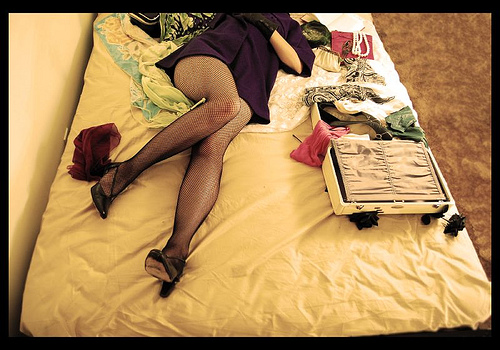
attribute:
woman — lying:
[124, 19, 286, 242]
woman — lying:
[145, 25, 297, 275]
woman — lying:
[173, 20, 300, 278]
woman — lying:
[118, 28, 300, 248]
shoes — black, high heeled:
[54, 175, 216, 303]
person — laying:
[114, 36, 333, 269]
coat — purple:
[181, 35, 290, 112]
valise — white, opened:
[314, 123, 443, 236]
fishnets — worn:
[118, 82, 267, 263]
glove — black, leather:
[235, 13, 280, 35]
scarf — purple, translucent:
[73, 134, 121, 174]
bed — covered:
[47, 47, 455, 316]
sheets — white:
[197, 205, 437, 332]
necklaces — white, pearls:
[338, 24, 379, 63]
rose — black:
[428, 207, 474, 243]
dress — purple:
[173, 17, 306, 114]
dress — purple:
[191, 27, 333, 144]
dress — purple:
[199, 21, 324, 111]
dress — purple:
[191, 25, 321, 116]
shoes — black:
[91, 182, 207, 304]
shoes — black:
[107, 148, 210, 287]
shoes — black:
[81, 150, 205, 280]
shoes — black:
[85, 137, 202, 307]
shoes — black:
[55, 130, 235, 345]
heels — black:
[71, 120, 207, 319]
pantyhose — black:
[114, 107, 277, 331]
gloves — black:
[254, 20, 286, 45]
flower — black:
[429, 181, 473, 244]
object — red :
[61, 118, 160, 245]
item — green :
[368, 110, 435, 161]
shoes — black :
[58, 149, 260, 348]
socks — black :
[102, 150, 169, 226]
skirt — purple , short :
[293, 104, 355, 200]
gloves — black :
[238, 21, 297, 44]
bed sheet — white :
[67, 26, 458, 334]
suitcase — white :
[303, 63, 457, 228]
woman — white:
[82, 0, 319, 300]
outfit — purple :
[167, 5, 337, 130]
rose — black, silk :
[447, 205, 464, 250]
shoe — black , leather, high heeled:
[90, 148, 127, 223]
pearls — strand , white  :
[348, 16, 376, 63]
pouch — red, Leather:
[324, 21, 381, 68]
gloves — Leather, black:
[229, 11, 282, 42]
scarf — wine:
[324, 30, 374, 66]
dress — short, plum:
[152, 4, 314, 131]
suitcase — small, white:
[320, 130, 450, 227]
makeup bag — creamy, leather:
[302, 43, 344, 76]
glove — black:
[229, 7, 276, 37]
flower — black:
[437, 204, 473, 237]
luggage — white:
[302, 79, 458, 234]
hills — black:
[99, 48, 251, 263]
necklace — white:
[346, 21, 376, 68]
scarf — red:
[66, 115, 126, 185]